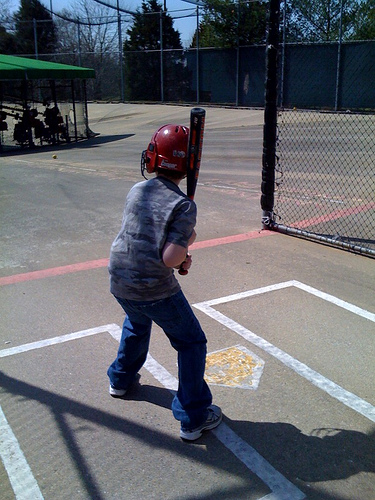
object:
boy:
[104, 125, 222, 443]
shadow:
[126, 384, 373, 486]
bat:
[177, 107, 206, 275]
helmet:
[140, 124, 189, 180]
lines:
[0, 322, 311, 500]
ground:
[0, 102, 372, 499]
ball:
[52, 153, 58, 159]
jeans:
[107, 290, 215, 427]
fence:
[0, 0, 375, 113]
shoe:
[179, 404, 223, 441]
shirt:
[107, 179, 198, 300]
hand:
[183, 251, 193, 270]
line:
[0, 201, 375, 286]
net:
[268, 0, 374, 259]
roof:
[0, 53, 96, 81]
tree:
[121, 0, 186, 103]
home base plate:
[200, 342, 265, 391]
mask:
[140, 149, 151, 181]